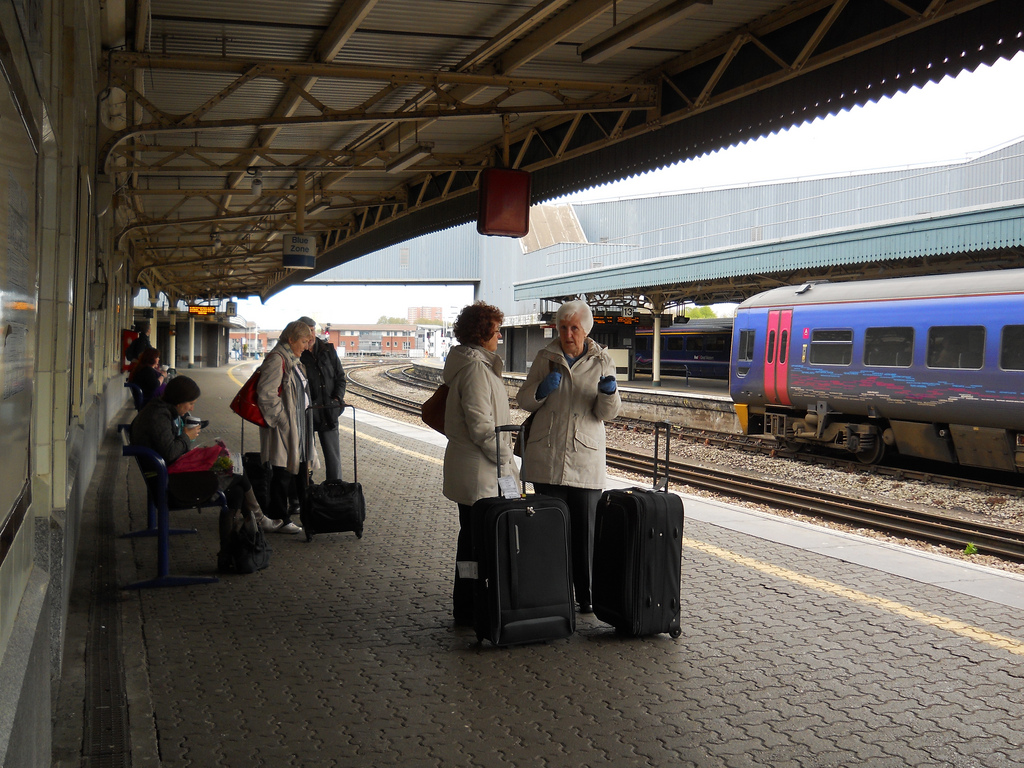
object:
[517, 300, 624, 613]
person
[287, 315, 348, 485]
person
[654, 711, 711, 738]
stone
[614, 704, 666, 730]
stone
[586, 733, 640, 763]
stone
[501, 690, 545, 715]
stone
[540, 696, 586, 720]
stone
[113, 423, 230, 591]
bench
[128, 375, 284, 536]
woman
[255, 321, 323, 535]
people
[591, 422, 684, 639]
suitcase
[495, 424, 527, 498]
handle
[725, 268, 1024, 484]
train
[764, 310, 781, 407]
doors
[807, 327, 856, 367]
window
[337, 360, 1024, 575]
tracks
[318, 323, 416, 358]
building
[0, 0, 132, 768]
wall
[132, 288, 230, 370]
building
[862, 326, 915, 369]
window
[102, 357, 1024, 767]
floor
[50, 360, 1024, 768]
platform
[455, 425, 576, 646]
suitcase